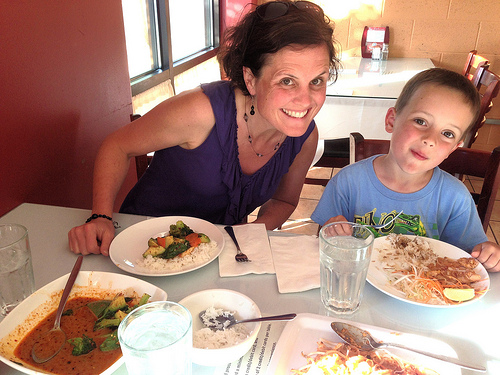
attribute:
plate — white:
[114, 211, 478, 320]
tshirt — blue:
[324, 166, 470, 256]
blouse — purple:
[164, 84, 282, 217]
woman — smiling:
[214, 5, 337, 167]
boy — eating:
[377, 62, 482, 202]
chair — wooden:
[343, 124, 499, 190]